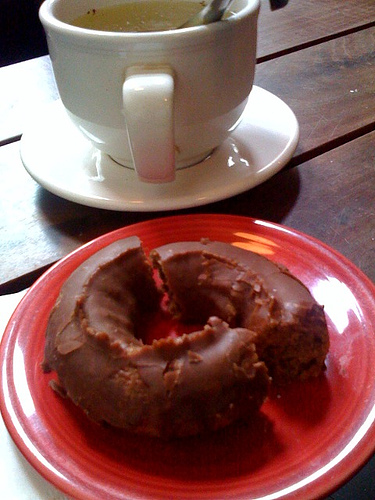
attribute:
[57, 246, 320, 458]
donut — split, choclate, brown, porcelain, red, large, 2 pieces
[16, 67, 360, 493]
foreground — red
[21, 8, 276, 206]
cup — white, liquid, beverage, soup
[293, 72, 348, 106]
table — wood, wooden, brown, small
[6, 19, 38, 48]
background — black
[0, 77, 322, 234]
plate — white, shiny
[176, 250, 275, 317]
chocolate — frosting, frosted, donut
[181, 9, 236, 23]
utensil — silver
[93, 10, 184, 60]
soup — yellowish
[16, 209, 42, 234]
glare — table